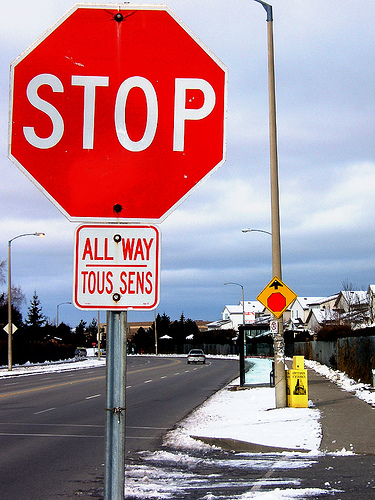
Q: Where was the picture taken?
A: It was taken at the road.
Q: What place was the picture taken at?
A: It was taken at the road.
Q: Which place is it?
A: It is a road.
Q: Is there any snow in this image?
A: Yes, there is snow.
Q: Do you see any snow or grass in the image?
A: Yes, there is snow.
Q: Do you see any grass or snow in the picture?
A: Yes, there is snow.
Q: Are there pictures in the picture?
A: No, there are no pictures.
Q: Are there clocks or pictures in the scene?
A: No, there are no pictures or clocks.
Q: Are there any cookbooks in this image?
A: No, there are no cookbooks.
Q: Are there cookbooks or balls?
A: No, there are no cookbooks or balls.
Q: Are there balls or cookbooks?
A: No, there are no cookbooks or balls.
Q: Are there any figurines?
A: No, there are no figurines.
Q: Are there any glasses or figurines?
A: No, there are no figurines or glasses.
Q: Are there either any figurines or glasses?
A: No, there are no figurines or glasses.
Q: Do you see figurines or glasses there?
A: No, there are no figurines or glasses.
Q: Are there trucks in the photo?
A: No, there are no trucks.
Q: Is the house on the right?
A: Yes, the house is on the right of the image.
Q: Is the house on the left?
A: No, the house is on the right of the image.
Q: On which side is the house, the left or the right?
A: The house is on the right of the image.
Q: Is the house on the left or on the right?
A: The house is on the right of the image.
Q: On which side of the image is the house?
A: The house is on the right of the image.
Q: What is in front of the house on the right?
A: The tree is in front of the house.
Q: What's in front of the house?
A: The tree is in front of the house.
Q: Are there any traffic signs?
A: Yes, there is a traffic sign.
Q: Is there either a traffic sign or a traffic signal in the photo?
A: Yes, there is a traffic sign.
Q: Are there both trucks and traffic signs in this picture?
A: No, there is a traffic sign but no trucks.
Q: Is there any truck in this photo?
A: No, there are no trucks.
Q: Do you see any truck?
A: No, there are no trucks.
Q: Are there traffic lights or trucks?
A: No, there are no trucks or traffic lights.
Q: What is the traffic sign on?
A: The traffic sign is on the pole.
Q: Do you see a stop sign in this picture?
A: Yes, there is a stop sign.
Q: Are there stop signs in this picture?
A: Yes, there is a stop sign.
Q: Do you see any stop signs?
A: Yes, there is a stop sign.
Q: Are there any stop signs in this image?
A: Yes, there is a stop sign.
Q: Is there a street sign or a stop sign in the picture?
A: Yes, there is a stop sign.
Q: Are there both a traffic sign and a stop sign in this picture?
A: Yes, there are both a stop sign and a traffic sign.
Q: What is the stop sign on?
A: The stop sign is on the pole.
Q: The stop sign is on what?
A: The stop sign is on the pole.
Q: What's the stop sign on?
A: The stop sign is on the pole.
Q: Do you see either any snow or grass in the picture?
A: Yes, there is snow.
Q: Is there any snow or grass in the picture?
A: Yes, there is snow.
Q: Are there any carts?
A: No, there are no carts.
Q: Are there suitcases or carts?
A: No, there are no carts or suitcases.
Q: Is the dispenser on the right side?
A: Yes, the dispenser is on the right of the image.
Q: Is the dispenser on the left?
A: No, the dispenser is on the right of the image.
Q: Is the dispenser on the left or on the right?
A: The dispenser is on the right of the image.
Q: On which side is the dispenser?
A: The dispenser is on the right of the image.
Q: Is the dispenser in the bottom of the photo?
A: Yes, the dispenser is in the bottom of the image.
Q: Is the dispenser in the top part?
A: No, the dispenser is in the bottom of the image.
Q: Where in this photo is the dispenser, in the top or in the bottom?
A: The dispenser is in the bottom of the image.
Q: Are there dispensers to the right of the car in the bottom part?
A: Yes, there is a dispenser to the right of the car.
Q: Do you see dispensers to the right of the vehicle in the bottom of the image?
A: Yes, there is a dispenser to the right of the car.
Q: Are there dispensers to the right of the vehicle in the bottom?
A: Yes, there is a dispenser to the right of the car.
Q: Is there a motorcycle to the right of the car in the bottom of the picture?
A: No, there is a dispenser to the right of the car.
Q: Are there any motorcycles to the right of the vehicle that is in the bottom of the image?
A: No, there is a dispenser to the right of the car.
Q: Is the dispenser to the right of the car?
A: Yes, the dispenser is to the right of the car.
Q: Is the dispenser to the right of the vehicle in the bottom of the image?
A: Yes, the dispenser is to the right of the car.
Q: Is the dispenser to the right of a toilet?
A: No, the dispenser is to the right of the car.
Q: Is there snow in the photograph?
A: Yes, there is snow.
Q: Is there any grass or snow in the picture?
A: Yes, there is snow.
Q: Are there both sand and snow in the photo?
A: No, there is snow but no sand.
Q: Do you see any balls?
A: No, there are no balls.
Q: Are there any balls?
A: No, there are no balls.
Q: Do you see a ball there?
A: No, there are no balls.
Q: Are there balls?
A: No, there are no balls.